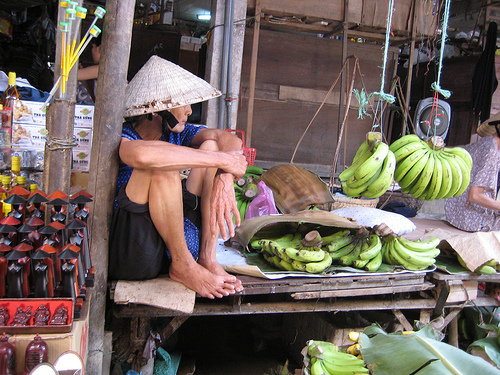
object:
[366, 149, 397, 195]
bananas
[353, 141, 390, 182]
bananas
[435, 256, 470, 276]
leaf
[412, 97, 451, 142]
fan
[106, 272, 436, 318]
table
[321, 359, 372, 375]
banana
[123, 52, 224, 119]
hat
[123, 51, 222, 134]
head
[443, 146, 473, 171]
bananas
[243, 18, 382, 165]
wall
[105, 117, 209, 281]
outfit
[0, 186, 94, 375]
box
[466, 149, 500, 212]
arm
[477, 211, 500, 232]
leg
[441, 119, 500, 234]
woman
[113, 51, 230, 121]
hat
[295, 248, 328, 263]
bananas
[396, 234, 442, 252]
bananas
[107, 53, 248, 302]
man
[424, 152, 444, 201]
bananas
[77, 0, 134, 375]
post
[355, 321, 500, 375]
leaf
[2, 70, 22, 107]
bottle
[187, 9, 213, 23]
light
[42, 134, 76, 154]
rope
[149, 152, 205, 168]
skin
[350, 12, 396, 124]
rope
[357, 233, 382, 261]
bananas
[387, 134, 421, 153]
bananas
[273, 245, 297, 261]
bananas